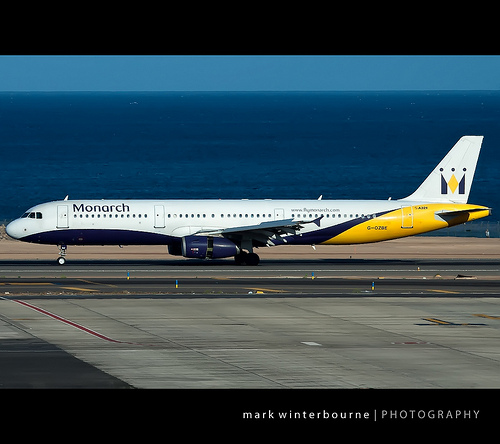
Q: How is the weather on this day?
A: It is clear.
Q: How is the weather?
A: It is clear.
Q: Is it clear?
A: Yes, it is clear.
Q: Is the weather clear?
A: Yes, it is clear.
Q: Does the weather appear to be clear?
A: Yes, it is clear.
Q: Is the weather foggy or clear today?
A: It is clear.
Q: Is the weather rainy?
A: No, it is clear.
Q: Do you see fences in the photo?
A: No, there are no fences.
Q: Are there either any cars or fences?
A: No, there are no fences or cars.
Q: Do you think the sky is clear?
A: Yes, the sky is clear.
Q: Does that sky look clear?
A: Yes, the sky is clear.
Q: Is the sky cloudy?
A: No, the sky is clear.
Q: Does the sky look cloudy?
A: No, the sky is clear.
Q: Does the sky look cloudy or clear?
A: The sky is clear.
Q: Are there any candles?
A: No, there are no candles.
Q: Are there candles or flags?
A: No, there are no candles or flags.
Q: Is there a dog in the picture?
A: No, there are no dogs.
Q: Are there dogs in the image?
A: No, there are no dogs.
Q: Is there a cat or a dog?
A: No, there are no dogs or cats.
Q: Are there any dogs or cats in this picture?
A: No, there are no dogs or cats.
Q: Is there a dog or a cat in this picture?
A: No, there are no dogs or cats.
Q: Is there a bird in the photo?
A: No, there are no birds.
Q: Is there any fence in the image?
A: No, there are no fences.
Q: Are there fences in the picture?
A: No, there are no fences.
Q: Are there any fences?
A: No, there are no fences.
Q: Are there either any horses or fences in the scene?
A: No, there are no fences or horses.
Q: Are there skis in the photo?
A: No, there are no skis.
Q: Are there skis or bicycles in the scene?
A: No, there are no skis or bicycles.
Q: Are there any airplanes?
A: Yes, there is an airplane.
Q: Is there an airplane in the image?
A: Yes, there is an airplane.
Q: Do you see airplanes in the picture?
A: Yes, there is an airplane.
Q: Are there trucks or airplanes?
A: Yes, there is an airplane.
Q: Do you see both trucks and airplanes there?
A: No, there is an airplane but no trucks.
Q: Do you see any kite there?
A: No, there are no kites.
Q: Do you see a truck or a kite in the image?
A: No, there are no kites or trucks.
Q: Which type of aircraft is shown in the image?
A: The aircraft is an airplane.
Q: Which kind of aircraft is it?
A: The aircraft is an airplane.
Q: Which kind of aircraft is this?
A: That is an airplane.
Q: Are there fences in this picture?
A: No, there are no fences.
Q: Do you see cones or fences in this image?
A: No, there are no fences or cones.